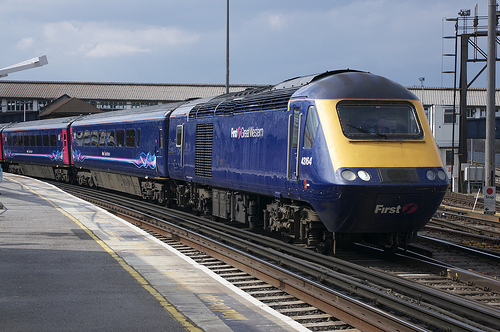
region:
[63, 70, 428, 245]
This is a train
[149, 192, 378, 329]
These are train tracks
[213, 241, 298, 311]
The tracks have rust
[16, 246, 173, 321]
This is a train platform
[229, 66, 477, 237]
The train is blue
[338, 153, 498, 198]
These are white lights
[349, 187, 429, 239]
The train says "First"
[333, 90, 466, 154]
This is a window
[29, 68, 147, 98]
This is a building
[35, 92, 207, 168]
These are train cars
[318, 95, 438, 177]
yellow front of train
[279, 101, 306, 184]
door on first train car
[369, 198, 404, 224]
white lettering on blue background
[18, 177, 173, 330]
yellow line painted on train platform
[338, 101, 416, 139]
front window of train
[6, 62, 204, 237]
three blue train cars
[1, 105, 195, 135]
gray roofs of train cars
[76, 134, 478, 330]
track train is traveling on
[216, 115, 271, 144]
white lettering on side of train car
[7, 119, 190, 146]
windows on side of train cars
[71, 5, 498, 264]
This is a long train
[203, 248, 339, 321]
This is a train track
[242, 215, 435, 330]
The track is made of steel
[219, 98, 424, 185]
The train has yellow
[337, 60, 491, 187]
This is the window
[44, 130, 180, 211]
These are train cars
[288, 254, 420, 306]
The tracks have rust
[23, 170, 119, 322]
This is a train platform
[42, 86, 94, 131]
This is a building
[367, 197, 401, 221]
the text saying first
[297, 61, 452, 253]
front of a train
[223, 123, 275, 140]
text on a train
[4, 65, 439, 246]
a blue train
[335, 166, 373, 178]
left headlight on train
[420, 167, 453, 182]
right side of train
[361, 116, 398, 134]
conductor of train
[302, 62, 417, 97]
front top of a train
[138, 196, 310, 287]
a steel railroad track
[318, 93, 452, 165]
yellow part of train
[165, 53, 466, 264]
Head of a train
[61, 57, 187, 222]
This is a bus of a train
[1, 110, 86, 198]
This is a bus of a train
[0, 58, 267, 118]
This is a house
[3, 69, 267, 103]
Roof of a house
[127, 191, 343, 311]
This is a railway line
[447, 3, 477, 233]
This is a pole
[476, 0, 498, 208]
This is a pole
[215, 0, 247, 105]
This is a pole